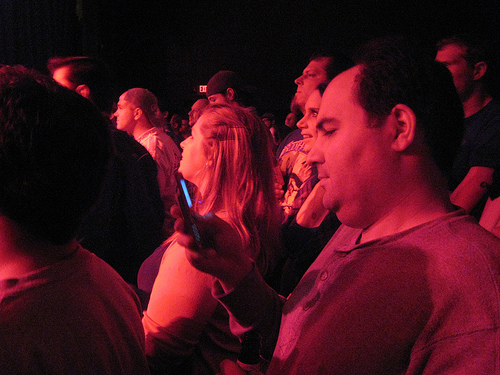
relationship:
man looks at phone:
[174, 47, 499, 374] [174, 173, 206, 247]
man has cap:
[202, 69, 271, 141] [204, 68, 253, 94]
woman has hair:
[132, 107, 277, 375] [197, 104, 281, 259]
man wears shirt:
[174, 47, 499, 374] [225, 216, 499, 373]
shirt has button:
[225, 216, 499, 373] [319, 273, 330, 280]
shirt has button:
[225, 216, 499, 373] [335, 246, 356, 263]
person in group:
[429, 38, 499, 224] [0, 41, 499, 375]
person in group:
[103, 81, 182, 214] [0, 41, 499, 375]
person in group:
[48, 57, 105, 129] [0, 41, 499, 375]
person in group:
[186, 97, 210, 126] [0, 41, 499, 375]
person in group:
[0, 66, 149, 375] [0, 41, 499, 375]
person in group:
[289, 56, 352, 141] [0, 41, 499, 375]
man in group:
[174, 47, 499, 374] [0, 41, 499, 375]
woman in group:
[132, 107, 277, 375] [0, 41, 499, 375]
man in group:
[202, 69, 271, 141] [0, 41, 499, 375]